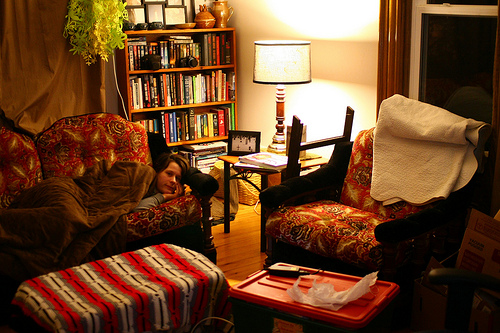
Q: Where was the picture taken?
A: In a living room.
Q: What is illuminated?
A: Lamp.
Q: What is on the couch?
A: A woman.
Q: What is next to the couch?
A: A table.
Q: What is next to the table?
A: A chair.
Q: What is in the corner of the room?
A: A bookcase.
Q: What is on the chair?
A: A blanket.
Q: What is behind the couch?
A: Drapes.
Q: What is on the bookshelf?
A: Books.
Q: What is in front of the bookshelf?
A: A table.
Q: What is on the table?
A: A lamp.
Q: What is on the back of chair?
A: A blanket.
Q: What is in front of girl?
A: A striped cover.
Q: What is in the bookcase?
A: Books and figurines.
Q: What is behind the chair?
A: A window.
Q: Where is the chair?
A: In a room.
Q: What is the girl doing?
A: Lying on sofa.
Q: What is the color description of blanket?
A: White.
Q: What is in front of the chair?
A: An orange container.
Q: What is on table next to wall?
A: A lamp.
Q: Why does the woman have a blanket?
A: She is cold.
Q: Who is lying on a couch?
A: A woman with a blanket.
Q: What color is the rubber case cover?
A: Orange.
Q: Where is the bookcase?
A: In the corner.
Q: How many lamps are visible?
A: One.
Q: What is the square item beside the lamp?
A: A picture in a frame.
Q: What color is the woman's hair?
A: Brown.